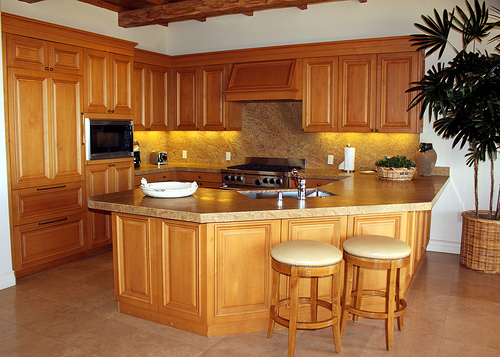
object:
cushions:
[269, 239, 343, 268]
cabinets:
[374, 51, 424, 129]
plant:
[403, 0, 500, 222]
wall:
[0, 0, 499, 258]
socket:
[225, 152, 233, 161]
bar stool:
[338, 234, 412, 349]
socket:
[327, 154, 333, 164]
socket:
[182, 150, 188, 159]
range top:
[227, 162, 301, 173]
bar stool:
[265, 238, 343, 354]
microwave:
[85, 118, 136, 163]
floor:
[0, 248, 499, 355]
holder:
[345, 144, 351, 174]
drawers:
[10, 180, 86, 229]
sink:
[230, 180, 334, 202]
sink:
[237, 186, 337, 199]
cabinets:
[299, 57, 335, 132]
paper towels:
[339, 147, 355, 171]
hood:
[222, 61, 305, 102]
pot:
[458, 209, 499, 276]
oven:
[221, 163, 303, 189]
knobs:
[220, 166, 248, 182]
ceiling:
[0, 0, 500, 56]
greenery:
[372, 155, 417, 168]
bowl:
[138, 177, 198, 198]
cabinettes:
[211, 219, 283, 318]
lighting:
[134, 126, 425, 146]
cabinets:
[335, 54, 375, 131]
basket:
[460, 210, 497, 274]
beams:
[112, 0, 342, 29]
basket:
[376, 166, 417, 181]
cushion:
[343, 234, 411, 260]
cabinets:
[194, 67, 226, 131]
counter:
[87, 162, 454, 336]